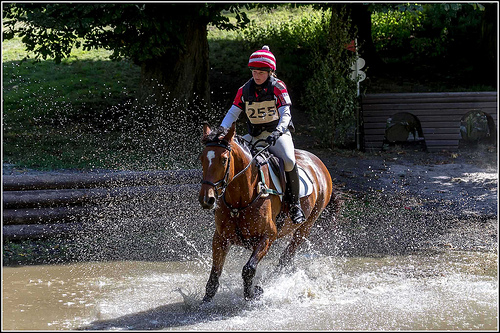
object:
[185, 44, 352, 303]
woman riding horse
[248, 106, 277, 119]
three-digit number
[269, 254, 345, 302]
splashed water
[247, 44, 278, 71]
knitted hat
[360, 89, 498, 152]
wooden barrier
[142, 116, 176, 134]
drops of water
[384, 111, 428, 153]
arched cutouts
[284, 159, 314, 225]
black boot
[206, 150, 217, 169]
white splotch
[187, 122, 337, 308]
horse in the water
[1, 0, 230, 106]
trees behind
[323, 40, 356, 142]
tall weed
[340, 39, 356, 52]
red flag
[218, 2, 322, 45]
sunshine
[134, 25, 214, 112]
tree trunk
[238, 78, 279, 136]
vest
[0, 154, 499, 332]
water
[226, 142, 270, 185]
reins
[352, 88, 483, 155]
wall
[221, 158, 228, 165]
eyes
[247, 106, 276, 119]
225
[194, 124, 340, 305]
horse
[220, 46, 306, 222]
girl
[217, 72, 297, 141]
jersey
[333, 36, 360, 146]
flag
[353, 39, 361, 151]
pole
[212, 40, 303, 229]
person